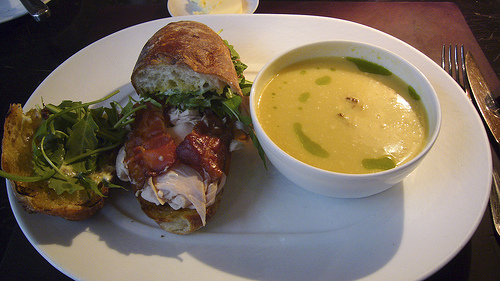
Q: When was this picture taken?
A: During working hours.